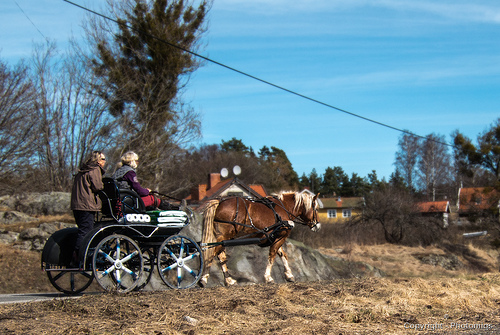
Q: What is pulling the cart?
A: A horse.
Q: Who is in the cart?
A: Two people.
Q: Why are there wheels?
A: So the cart can roll.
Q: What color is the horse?
A: Brown.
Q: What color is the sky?
A: Blue.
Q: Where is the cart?
A: Behind the horse.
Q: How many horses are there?
A: One.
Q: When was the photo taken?
A: Daytime.